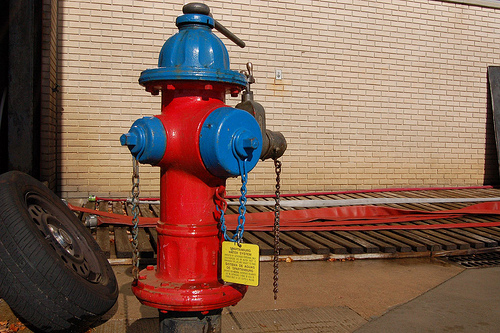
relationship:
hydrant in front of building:
[119, 2, 288, 333] [0, 0, 499, 195]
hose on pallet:
[67, 202, 497, 231] [80, 185, 499, 260]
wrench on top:
[182, 1, 246, 49] [137, 3, 255, 84]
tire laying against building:
[0, 168, 121, 333] [0, 0, 499, 195]